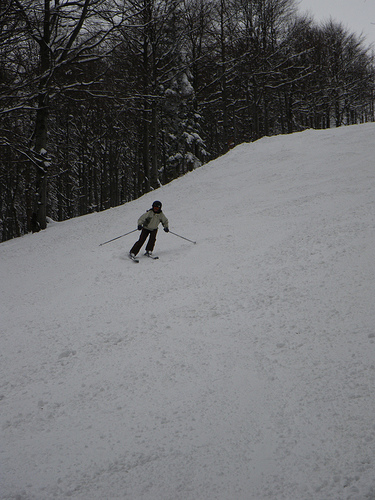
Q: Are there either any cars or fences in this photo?
A: No, there are no cars or fences.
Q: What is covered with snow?
A: The tree is covered with snow.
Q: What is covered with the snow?
A: The tree is covered with snow.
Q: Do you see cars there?
A: No, there are no cars.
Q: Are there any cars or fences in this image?
A: No, there are no cars or fences.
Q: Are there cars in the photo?
A: No, there are no cars.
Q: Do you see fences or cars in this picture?
A: No, there are no cars or fences.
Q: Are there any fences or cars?
A: No, there are no cars or fences.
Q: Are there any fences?
A: No, there are no fences.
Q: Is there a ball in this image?
A: No, there are no balls.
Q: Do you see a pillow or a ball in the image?
A: No, there are no balls or pillows.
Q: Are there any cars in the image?
A: No, there are no cars.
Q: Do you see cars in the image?
A: No, there are no cars.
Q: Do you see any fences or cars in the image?
A: No, there are no cars or fences.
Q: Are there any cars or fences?
A: No, there are no cars or fences.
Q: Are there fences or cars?
A: No, there are no cars or fences.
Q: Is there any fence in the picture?
A: No, there are no fences.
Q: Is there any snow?
A: Yes, there is snow.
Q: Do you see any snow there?
A: Yes, there is snow.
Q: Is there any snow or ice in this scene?
A: Yes, there is snow.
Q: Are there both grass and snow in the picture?
A: No, there is snow but no grass.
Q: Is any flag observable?
A: No, there are no flags.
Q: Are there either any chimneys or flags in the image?
A: No, there are no flags or chimneys.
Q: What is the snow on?
A: The snow is on the tree.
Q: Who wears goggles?
A: The skier wears goggles.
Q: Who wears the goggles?
A: The skier wears goggles.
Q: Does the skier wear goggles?
A: Yes, the skier wears goggles.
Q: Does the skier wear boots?
A: No, the skier wears goggles.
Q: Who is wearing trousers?
A: The skier is wearing trousers.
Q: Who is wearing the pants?
A: The skier is wearing trousers.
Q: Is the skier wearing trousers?
A: Yes, the skier is wearing trousers.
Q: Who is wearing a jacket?
A: The skier is wearing a jacket.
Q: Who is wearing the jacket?
A: The skier is wearing a jacket.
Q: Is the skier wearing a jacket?
A: Yes, the skier is wearing a jacket.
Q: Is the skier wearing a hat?
A: No, the skier is wearing a jacket.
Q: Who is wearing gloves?
A: The skier is wearing gloves.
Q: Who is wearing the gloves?
A: The skier is wearing gloves.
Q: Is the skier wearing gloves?
A: Yes, the skier is wearing gloves.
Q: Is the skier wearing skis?
A: No, the skier is wearing gloves.